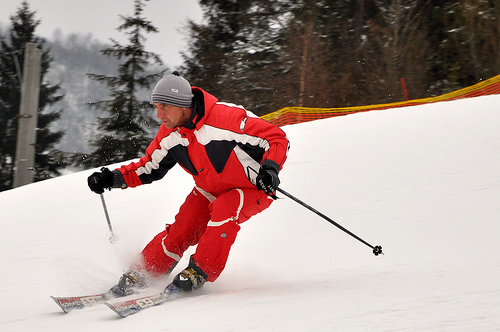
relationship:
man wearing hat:
[22, 67, 394, 316] [147, 71, 194, 107]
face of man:
[155, 103, 176, 127] [22, 67, 394, 316]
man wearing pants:
[22, 67, 394, 316] [142, 195, 274, 279]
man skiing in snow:
[22, 67, 394, 316] [396, 119, 477, 191]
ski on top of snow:
[52, 287, 107, 310] [396, 119, 477, 191]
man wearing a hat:
[22, 67, 394, 316] [147, 71, 194, 107]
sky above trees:
[62, 5, 107, 28] [204, 1, 499, 100]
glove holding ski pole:
[251, 158, 288, 193] [96, 195, 123, 244]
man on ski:
[50, 74, 386, 315] [52, 287, 107, 310]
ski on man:
[52, 287, 107, 310] [50, 74, 386, 315]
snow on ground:
[396, 119, 477, 191] [386, 108, 493, 329]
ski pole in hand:
[96, 195, 123, 244] [255, 160, 280, 190]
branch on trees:
[279, 26, 322, 82] [204, 1, 499, 100]